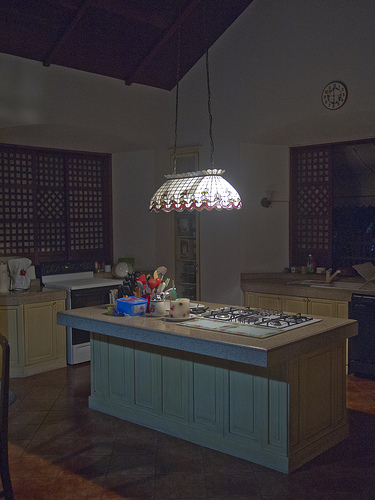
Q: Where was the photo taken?
A: In a room.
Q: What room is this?
A: Kitchen.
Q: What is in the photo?
A: A stove.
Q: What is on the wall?
A: A clock.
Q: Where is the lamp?
A: On the ceiling.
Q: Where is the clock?
A: On the wall.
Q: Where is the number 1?
A: On the clock.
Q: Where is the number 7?
A: On the clock.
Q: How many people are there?
A: None.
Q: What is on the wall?
A: A clock.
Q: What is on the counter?
A: A stove.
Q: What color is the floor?
A: Red.